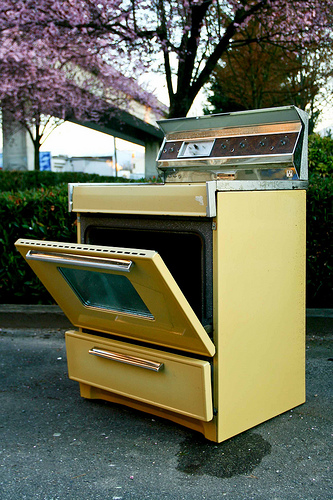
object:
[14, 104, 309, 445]
stove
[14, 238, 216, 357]
door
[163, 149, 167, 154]
knobs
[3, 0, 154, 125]
flowers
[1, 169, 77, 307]
bushes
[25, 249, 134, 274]
handle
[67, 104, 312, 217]
silver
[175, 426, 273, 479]
liquid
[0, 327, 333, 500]
ground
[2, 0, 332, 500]
outside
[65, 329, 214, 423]
drawer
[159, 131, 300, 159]
dials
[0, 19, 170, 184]
building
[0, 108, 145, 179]
window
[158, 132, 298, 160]
panel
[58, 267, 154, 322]
window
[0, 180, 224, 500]
foreground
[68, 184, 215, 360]
oven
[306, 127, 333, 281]
bush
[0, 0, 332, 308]
background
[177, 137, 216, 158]
clock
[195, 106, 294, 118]
top light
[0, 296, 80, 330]
curb